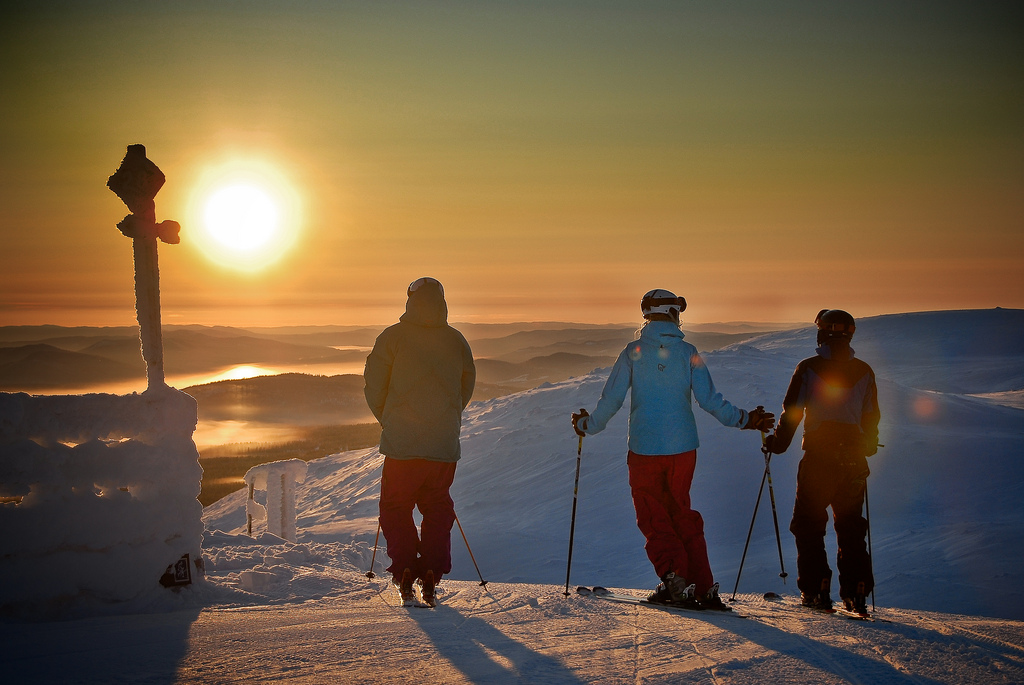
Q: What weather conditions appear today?
A: It is clear.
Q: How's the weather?
A: It is clear.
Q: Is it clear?
A: Yes, it is clear.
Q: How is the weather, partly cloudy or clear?
A: It is clear.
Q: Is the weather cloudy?
A: No, it is clear.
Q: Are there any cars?
A: No, there are no cars.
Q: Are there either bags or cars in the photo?
A: No, there are no cars or bags.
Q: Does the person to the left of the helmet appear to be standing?
A: Yes, the person is standing.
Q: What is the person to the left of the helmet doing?
A: The person is standing.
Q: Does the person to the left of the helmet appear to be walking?
A: No, the person is standing.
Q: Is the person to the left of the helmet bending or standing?
A: The person is standing.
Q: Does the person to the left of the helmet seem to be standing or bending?
A: The person is standing.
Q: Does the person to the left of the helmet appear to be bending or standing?
A: The person is standing.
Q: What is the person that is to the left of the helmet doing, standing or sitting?
A: The person is standing.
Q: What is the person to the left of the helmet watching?
A: The person is watching the sun.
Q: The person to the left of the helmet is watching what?
A: The person is watching the sun.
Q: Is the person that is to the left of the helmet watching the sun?
A: Yes, the person is watching the sun.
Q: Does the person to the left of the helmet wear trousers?
A: Yes, the person wears trousers.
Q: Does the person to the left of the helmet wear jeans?
A: No, the person wears trousers.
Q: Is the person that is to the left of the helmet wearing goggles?
A: Yes, the person is wearing goggles.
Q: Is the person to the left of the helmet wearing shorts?
A: No, the person is wearing goggles.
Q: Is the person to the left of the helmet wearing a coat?
A: Yes, the person is wearing a coat.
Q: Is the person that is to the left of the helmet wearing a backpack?
A: No, the person is wearing a coat.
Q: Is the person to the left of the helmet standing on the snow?
A: Yes, the person is standing on the snow.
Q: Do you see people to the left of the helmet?
A: Yes, there is a person to the left of the helmet.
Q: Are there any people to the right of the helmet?
A: No, the person is to the left of the helmet.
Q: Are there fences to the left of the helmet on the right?
A: No, there is a person to the left of the helmet.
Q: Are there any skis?
A: Yes, there are skis.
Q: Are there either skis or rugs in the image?
A: Yes, there are skis.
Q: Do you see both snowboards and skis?
A: No, there are skis but no snowboards.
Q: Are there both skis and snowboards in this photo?
A: No, there are skis but no snowboards.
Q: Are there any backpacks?
A: No, there are no backpacks.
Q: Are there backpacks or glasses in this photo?
A: No, there are no backpacks or glasses.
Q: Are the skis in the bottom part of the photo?
A: Yes, the skis are in the bottom of the image.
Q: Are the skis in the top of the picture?
A: No, the skis are in the bottom of the image.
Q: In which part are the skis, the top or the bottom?
A: The skis are in the bottom of the image.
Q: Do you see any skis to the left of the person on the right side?
A: Yes, there are skis to the left of the person.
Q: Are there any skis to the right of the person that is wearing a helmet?
A: No, the skis are to the left of the person.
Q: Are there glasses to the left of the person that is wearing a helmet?
A: No, there are skis to the left of the person.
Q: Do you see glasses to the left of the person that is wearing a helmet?
A: No, there are skis to the left of the person.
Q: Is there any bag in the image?
A: No, there are no bags.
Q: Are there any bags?
A: No, there are no bags.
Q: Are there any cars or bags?
A: No, there are no bags or cars.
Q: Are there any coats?
A: Yes, there is a coat.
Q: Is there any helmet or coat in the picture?
A: Yes, there is a coat.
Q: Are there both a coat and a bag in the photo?
A: No, there is a coat but no bags.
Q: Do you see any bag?
A: No, there are no bags.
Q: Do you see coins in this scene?
A: No, there are no coins.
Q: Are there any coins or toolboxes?
A: No, there are no coins or toolboxes.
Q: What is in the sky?
A: The sun is in the sky.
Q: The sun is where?
A: The sun is in the sky.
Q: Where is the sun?
A: The sun is in the sky.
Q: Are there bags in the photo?
A: No, there are no bags.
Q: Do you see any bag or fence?
A: No, there are no bags or fences.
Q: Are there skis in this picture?
A: Yes, there are skis.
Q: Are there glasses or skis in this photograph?
A: Yes, there are skis.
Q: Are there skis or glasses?
A: Yes, there are skis.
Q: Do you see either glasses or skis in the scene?
A: Yes, there are skis.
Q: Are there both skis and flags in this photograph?
A: No, there are skis but no flags.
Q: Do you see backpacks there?
A: No, there are no backpacks.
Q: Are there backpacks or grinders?
A: No, there are no backpacks or grinders.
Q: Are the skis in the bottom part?
A: Yes, the skis are in the bottom of the image.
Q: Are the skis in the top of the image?
A: No, the skis are in the bottom of the image.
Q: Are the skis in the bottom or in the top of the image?
A: The skis are in the bottom of the image.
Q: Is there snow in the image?
A: Yes, there is snow.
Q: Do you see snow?
A: Yes, there is snow.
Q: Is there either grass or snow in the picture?
A: Yes, there is snow.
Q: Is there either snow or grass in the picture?
A: Yes, there is snow.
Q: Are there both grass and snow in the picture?
A: No, there is snow but no grass.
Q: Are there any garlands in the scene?
A: No, there are no garlands.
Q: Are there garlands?
A: No, there are no garlands.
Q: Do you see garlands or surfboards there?
A: No, there are no garlands or surfboards.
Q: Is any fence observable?
A: No, there are no fences.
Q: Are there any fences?
A: No, there are no fences.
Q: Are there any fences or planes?
A: No, there are no fences or planes.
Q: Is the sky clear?
A: Yes, the sky is clear.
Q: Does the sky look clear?
A: Yes, the sky is clear.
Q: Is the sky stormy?
A: No, the sky is clear.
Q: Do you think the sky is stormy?
A: No, the sky is clear.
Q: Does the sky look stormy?
A: No, the sky is clear.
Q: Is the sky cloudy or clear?
A: The sky is clear.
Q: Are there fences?
A: No, there are no fences.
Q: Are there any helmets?
A: Yes, there is a helmet.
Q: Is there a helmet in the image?
A: Yes, there is a helmet.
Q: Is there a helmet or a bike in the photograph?
A: Yes, there is a helmet.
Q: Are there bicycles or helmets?
A: Yes, there is a helmet.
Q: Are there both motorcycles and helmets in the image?
A: No, there is a helmet but no motorcycles.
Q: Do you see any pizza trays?
A: No, there are no pizza trays.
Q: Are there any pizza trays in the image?
A: No, there are no pizza trays.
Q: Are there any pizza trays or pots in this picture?
A: No, there are no pizza trays or pots.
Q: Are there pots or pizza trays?
A: No, there are no pizza trays or pots.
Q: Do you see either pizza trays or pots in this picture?
A: No, there are no pizza trays or pots.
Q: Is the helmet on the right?
A: Yes, the helmet is on the right of the image.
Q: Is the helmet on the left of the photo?
A: No, the helmet is on the right of the image.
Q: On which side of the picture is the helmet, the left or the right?
A: The helmet is on the right of the image.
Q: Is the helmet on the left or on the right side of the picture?
A: The helmet is on the right of the image.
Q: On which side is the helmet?
A: The helmet is on the right of the image.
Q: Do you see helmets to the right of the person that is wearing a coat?
A: Yes, there is a helmet to the right of the person.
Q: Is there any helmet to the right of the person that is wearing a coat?
A: Yes, there is a helmet to the right of the person.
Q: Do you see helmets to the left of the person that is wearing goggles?
A: No, the helmet is to the right of the person.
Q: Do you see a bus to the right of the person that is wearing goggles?
A: No, there is a helmet to the right of the person.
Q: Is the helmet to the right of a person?
A: Yes, the helmet is to the right of a person.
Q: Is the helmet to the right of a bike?
A: No, the helmet is to the right of a person.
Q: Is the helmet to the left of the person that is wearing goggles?
A: No, the helmet is to the right of the person.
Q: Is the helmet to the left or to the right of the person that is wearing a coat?
A: The helmet is to the right of the person.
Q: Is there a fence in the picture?
A: No, there are no fences.